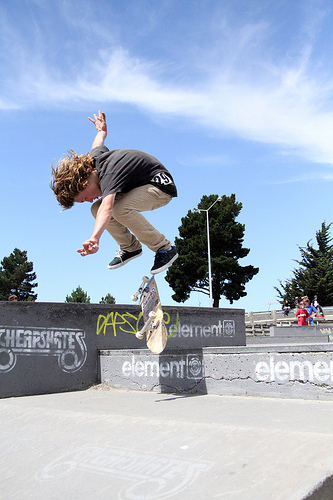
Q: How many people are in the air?
A: One.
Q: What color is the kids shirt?
A: Black.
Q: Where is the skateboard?
A: In mid air.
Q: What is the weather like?
A: Sunny.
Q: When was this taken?
A: During the day.